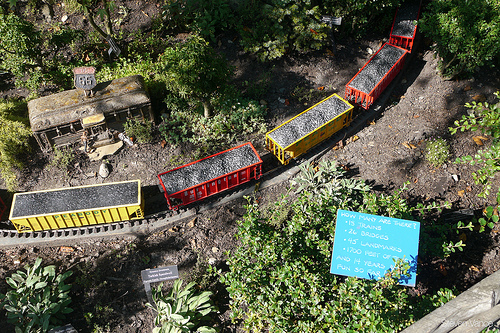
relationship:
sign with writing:
[328, 204, 423, 291] [337, 209, 418, 278]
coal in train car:
[8, 177, 140, 220] [7, 176, 150, 236]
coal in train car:
[158, 141, 262, 197] [7, 176, 150, 236]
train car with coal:
[153, 136, 266, 215] [158, 141, 262, 197]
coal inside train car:
[8, 177, 140, 220] [7, 176, 150, 236]